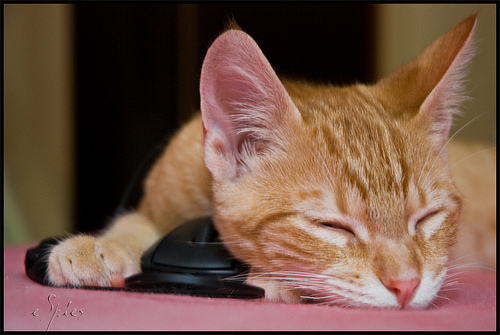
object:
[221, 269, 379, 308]
whisker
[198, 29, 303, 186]
ear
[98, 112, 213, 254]
leg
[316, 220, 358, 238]
closed eye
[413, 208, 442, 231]
closed eye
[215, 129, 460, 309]
face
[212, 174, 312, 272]
right cheek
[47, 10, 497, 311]
cat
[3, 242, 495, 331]
surface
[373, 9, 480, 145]
ear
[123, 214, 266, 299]
black mouse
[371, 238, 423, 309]
nose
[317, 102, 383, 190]
fur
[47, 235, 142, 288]
paw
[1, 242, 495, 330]
pad